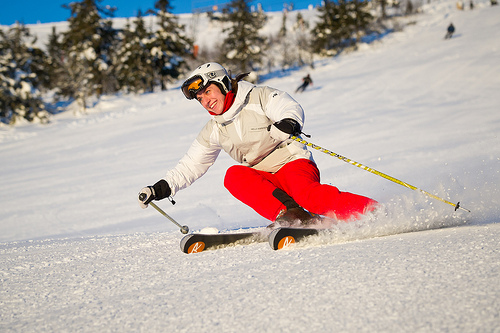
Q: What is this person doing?
A: Skiing.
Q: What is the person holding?
A: Ski poles.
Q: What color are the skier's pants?
A: Red.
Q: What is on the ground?
A: Snow.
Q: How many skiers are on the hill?
A: Three.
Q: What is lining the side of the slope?
A: Trees.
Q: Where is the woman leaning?
A: To the right.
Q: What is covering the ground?
A: Snow.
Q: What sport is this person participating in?
A: Skiing.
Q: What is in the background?
A: Trees.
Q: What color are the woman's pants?
A: Red.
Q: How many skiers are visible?
A: 3.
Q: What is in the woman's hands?
A: Ski poles.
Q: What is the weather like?
A: Cold and sunny.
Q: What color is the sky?
A: Blue.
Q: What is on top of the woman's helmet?
A: Goggles.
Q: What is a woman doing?
A: Skiing.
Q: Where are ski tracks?
A: On the snow.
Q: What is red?
A: Skiers pants.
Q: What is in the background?
A: Trees.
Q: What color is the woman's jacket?
A: White.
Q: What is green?
A: Trees.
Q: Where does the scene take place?
A: On ski slope.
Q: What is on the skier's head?
A: Helmet.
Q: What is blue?
A: Sky.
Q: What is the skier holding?
A: Ski poles.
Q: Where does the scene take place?
A: On a ski slope.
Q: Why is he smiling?
A: He likes skiing.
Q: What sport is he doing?
A: Downhill skiing.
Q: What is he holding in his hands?
A: Ski poles.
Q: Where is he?
A: A snowy slope.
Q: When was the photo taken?
A: Daytime.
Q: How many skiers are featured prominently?
A: One.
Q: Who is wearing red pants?
A: The skier in front.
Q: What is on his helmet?
A: His goggles.